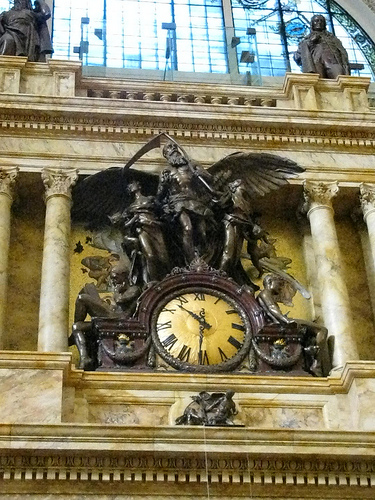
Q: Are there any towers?
A: No, there are no towers.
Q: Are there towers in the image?
A: No, there are no towers.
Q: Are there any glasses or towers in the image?
A: No, there are no towers or glasses.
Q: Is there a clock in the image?
A: Yes, there is a clock.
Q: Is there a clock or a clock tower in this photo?
A: Yes, there is a clock.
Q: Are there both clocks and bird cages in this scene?
A: No, there is a clock but no bird cages.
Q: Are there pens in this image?
A: No, there are no pens.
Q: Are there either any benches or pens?
A: No, there are no pens or benches.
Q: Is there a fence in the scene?
A: No, there are no fences.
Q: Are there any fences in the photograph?
A: No, there are no fences.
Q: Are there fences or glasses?
A: No, there are no fences or glasses.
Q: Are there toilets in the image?
A: No, there are no toilets.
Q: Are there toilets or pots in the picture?
A: No, there are no toilets or pots.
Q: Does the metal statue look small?
A: Yes, the statue is small.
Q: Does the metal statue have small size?
A: Yes, the statue is small.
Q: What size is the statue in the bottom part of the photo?
A: The statue is small.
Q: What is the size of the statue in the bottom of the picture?
A: The statue is small.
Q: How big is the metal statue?
A: The statue is small.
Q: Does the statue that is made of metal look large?
A: No, the statue is small.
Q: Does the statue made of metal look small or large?
A: The statue is small.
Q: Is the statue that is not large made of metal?
A: Yes, the statue is made of metal.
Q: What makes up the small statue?
A: The statue is made of metal.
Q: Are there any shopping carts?
A: No, there are no shopping carts.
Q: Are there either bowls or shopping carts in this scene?
A: No, there are no shopping carts or bowls.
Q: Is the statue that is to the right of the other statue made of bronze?
A: Yes, the statue is made of bronze.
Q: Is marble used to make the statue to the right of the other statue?
A: No, the statue is made of bronze.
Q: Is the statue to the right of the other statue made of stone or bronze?
A: The statue is made of bronze.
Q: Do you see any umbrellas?
A: No, there are no umbrellas.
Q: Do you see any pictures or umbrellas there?
A: No, there are no umbrellas or pictures.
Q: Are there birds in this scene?
A: No, there are no birds.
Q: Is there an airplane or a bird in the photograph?
A: No, there are no birds or airplanes.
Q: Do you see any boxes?
A: No, there are no boxes.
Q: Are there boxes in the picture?
A: No, there are no boxes.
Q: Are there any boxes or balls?
A: No, there are no boxes or balls.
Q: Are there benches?
A: No, there are no benches.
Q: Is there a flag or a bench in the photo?
A: No, there are no benches or flags.